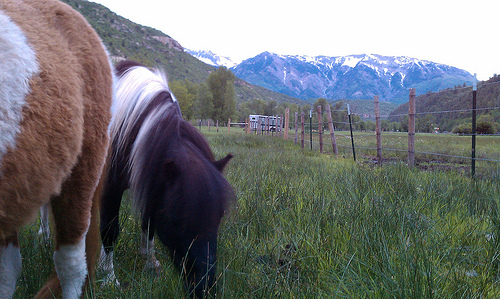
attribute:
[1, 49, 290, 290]
horses — are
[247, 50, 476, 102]
snow — white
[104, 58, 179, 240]
hair — white 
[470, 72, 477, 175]
post — black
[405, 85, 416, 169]
post — black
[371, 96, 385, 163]
post — black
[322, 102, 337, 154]
post — black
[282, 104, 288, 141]
post — black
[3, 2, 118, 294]
animal — brown, white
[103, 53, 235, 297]
animal — white, brown